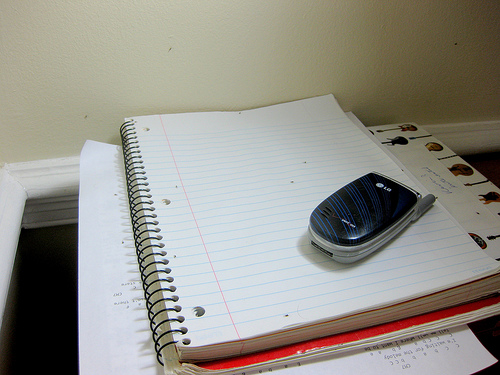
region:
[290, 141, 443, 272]
Cell phone on a notebook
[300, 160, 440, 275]
Cell phone is old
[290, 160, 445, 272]
Cell phone has a cover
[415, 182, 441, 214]
Antenna of phone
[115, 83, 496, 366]
Notebook under a phone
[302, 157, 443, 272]
Phone is wireless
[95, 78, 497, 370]
Notebook is open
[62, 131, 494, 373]
White sheet under notebook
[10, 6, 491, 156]
Wall behind desk is tan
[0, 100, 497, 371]
Furniture has glass surface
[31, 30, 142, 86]
wall is white in color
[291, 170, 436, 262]
mobile is grey in color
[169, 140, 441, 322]
mobile is kept on the notebook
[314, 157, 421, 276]
LG is the mobile company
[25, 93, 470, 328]
indoor picture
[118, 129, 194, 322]
spiral is black color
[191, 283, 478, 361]
book is red color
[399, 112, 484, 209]
picture sticker is under the book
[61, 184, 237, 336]
paper is kept under the notebook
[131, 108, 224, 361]
three separate holes are in notebook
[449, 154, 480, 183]
picture of man on postage stamp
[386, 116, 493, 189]
book of postage stamp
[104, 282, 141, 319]
words on white paper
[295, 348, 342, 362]
small spot on orange paper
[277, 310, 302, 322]
small spot on white paper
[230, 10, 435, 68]
tan walls in the background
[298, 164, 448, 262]
silver dark blue cell phone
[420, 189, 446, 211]
small tan edge of phone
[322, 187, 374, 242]
blue lines across cell phone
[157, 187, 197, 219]
small holes in note book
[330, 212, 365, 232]
white words on blue cell phone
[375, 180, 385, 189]
small circle on cell phone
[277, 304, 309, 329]
small black spot on writing paper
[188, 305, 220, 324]
small hole in note book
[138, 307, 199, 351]
wire mesh in notebook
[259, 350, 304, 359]
orange cover on notebook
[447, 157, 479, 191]
picture on book of stamps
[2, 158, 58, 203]
white edge of room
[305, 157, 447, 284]
shiny blue cell phone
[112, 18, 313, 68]
white wall in corner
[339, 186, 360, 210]
black line on cell phone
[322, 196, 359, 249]
blue stripes on phone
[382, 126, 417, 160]
black person on stamp booklet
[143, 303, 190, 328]
silver spiral in notebook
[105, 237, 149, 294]
writing on white paper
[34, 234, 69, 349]
dark brown wood flooring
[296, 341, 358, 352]
orange book cove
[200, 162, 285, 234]
lines in notebook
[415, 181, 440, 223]
silver tip of cell phone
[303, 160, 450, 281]
blue cell phone with silver trim